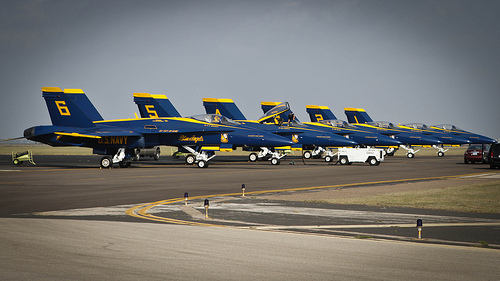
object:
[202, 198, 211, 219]
lights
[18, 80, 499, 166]
plane row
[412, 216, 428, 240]
light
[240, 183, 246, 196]
light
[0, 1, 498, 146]
sky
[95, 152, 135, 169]
gear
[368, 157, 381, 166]
wheel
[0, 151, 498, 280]
road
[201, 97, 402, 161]
jet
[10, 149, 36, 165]
item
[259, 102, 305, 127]
cockpit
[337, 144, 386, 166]
car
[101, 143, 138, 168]
landing gear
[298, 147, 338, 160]
landing gear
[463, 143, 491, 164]
vehicle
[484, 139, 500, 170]
suv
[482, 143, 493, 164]
door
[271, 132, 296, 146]
nose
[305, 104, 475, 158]
jet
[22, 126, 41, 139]
afterburner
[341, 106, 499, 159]
jet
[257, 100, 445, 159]
jet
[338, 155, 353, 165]
wheels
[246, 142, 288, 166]
landing gear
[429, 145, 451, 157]
landing gear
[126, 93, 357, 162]
jet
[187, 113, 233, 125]
window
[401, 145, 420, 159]
landing gear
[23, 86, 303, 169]
jet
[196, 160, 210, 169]
wheel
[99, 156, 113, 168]
wheel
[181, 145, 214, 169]
landing gear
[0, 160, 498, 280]
tarmac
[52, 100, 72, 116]
number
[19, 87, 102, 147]
tail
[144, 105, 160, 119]
5